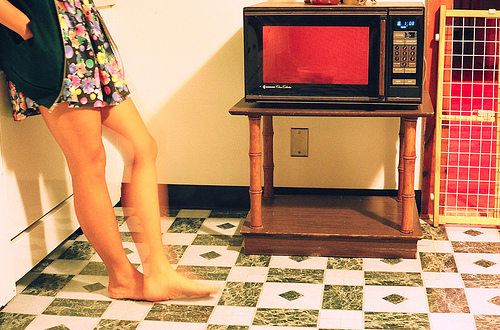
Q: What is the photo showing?
A: It is showing a kitchen.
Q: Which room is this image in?
A: It is at the kitchen.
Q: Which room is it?
A: It is a kitchen.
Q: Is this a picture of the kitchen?
A: Yes, it is showing the kitchen.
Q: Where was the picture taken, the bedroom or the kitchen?
A: It was taken at the kitchen.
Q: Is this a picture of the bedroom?
A: No, the picture is showing the kitchen.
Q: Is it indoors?
A: Yes, it is indoors.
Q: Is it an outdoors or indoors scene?
A: It is indoors.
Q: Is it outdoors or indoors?
A: It is indoors.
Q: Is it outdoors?
A: No, it is indoors.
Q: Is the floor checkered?
A: Yes, the floor is checkered.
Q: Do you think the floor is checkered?
A: Yes, the floor is checkered.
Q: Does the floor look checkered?
A: Yes, the floor is checkered.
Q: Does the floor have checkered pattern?
A: Yes, the floor is checkered.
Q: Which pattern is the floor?
A: The floor is checkered.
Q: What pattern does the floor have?
A: The floor has checkered pattern.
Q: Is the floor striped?
A: No, the floor is checkered.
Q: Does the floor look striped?
A: No, the floor is checkered.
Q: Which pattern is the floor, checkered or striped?
A: The floor is checkered.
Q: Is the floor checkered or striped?
A: The floor is checkered.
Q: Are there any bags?
A: No, there are no bags.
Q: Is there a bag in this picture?
A: No, there are no bags.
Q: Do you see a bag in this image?
A: No, there are no bags.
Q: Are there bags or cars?
A: No, there are no bags or cars.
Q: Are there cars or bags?
A: No, there are no bags or cars.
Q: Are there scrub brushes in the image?
A: No, there are no scrub brushes.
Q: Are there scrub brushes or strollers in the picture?
A: No, there are no scrub brushes or strollers.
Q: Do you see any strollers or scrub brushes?
A: No, there are no scrub brushes or strollers.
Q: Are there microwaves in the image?
A: Yes, there is a microwave.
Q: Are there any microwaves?
A: Yes, there is a microwave.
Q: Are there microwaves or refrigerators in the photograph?
A: Yes, there is a microwave.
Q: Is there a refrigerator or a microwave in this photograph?
A: Yes, there is a microwave.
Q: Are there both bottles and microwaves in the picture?
A: No, there is a microwave but no bottles.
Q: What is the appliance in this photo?
A: The appliance is a microwave.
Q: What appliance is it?
A: The appliance is a microwave.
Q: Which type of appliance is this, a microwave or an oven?
A: This is a microwave.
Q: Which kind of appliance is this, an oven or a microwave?
A: This is a microwave.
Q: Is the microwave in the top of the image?
A: Yes, the microwave is in the top of the image.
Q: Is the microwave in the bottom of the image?
A: No, the microwave is in the top of the image.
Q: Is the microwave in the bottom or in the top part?
A: The microwave is in the top of the image.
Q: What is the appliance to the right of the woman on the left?
A: The appliance is a microwave.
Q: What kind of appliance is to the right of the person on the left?
A: The appliance is a microwave.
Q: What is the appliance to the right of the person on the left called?
A: The appliance is a microwave.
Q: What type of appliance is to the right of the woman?
A: The appliance is a microwave.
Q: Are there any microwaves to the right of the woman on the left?
A: Yes, there is a microwave to the right of the woman.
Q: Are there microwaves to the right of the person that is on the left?
A: Yes, there is a microwave to the right of the woman.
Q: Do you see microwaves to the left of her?
A: No, the microwave is to the right of the woman.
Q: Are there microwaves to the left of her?
A: No, the microwave is to the right of the woman.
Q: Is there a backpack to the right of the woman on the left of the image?
A: No, there is a microwave to the right of the woman.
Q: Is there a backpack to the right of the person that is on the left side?
A: No, there is a microwave to the right of the woman.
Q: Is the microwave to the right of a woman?
A: Yes, the microwave is to the right of a woman.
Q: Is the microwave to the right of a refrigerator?
A: No, the microwave is to the right of a woman.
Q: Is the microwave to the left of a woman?
A: No, the microwave is to the right of a woman.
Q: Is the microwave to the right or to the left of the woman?
A: The microwave is to the right of the woman.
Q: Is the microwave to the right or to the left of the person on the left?
A: The microwave is to the right of the woman.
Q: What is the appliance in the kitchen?
A: The appliance is a microwave.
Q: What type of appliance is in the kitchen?
A: The appliance is a microwave.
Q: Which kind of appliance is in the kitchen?
A: The appliance is a microwave.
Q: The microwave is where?
A: The microwave is in the kitchen.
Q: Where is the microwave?
A: The microwave is in the kitchen.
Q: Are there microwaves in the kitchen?
A: Yes, there is a microwave in the kitchen.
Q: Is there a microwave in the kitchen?
A: Yes, there is a microwave in the kitchen.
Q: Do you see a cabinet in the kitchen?
A: No, there is a microwave in the kitchen.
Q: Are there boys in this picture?
A: No, there are no boys.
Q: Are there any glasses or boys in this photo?
A: No, there are no boys or glasses.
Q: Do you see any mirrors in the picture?
A: No, there are no mirrors.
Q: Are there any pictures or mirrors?
A: No, there are no mirrors or pictures.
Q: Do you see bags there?
A: No, there are no bags.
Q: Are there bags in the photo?
A: No, there are no bags.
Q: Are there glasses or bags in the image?
A: No, there are no bags or glasses.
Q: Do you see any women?
A: Yes, there is a woman.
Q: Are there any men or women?
A: Yes, there is a woman.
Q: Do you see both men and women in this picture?
A: No, there is a woman but no men.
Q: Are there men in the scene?
A: No, there are no men.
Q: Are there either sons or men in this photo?
A: No, there are no men or sons.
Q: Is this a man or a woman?
A: This is a woman.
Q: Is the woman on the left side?
A: Yes, the woman is on the left of the image.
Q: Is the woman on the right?
A: No, the woman is on the left of the image.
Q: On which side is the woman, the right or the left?
A: The woman is on the left of the image.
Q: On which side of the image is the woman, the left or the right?
A: The woman is on the left of the image.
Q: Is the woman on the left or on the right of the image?
A: The woman is on the left of the image.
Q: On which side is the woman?
A: The woman is on the left of the image.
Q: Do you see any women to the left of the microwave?
A: Yes, there is a woman to the left of the microwave.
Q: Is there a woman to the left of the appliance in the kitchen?
A: Yes, there is a woman to the left of the microwave.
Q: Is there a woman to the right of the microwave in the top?
A: No, the woman is to the left of the microwave.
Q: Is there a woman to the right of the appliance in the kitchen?
A: No, the woman is to the left of the microwave.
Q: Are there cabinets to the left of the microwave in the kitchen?
A: No, there is a woman to the left of the microwave.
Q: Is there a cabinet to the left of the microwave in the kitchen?
A: No, there is a woman to the left of the microwave.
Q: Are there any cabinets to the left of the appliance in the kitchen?
A: No, there is a woman to the left of the microwave.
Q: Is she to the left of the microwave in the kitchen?
A: Yes, the woman is to the left of the microwave.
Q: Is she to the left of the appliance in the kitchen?
A: Yes, the woman is to the left of the microwave.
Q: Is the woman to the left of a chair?
A: No, the woman is to the left of the microwave.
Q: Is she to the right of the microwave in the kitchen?
A: No, the woman is to the left of the microwave.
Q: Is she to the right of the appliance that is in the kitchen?
A: No, the woman is to the left of the microwave.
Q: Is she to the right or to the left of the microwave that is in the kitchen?
A: The woman is to the left of the microwave.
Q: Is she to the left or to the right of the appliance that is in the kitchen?
A: The woman is to the left of the microwave.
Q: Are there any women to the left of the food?
A: Yes, there is a woman to the left of the food.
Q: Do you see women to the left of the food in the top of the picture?
A: Yes, there is a woman to the left of the food.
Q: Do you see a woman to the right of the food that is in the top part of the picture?
A: No, the woman is to the left of the food.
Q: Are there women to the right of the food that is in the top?
A: No, the woman is to the left of the food.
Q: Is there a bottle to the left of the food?
A: No, there is a woman to the left of the food.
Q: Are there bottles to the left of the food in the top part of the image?
A: No, there is a woman to the left of the food.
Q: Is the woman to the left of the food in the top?
A: Yes, the woman is to the left of the food.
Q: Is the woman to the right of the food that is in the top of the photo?
A: No, the woman is to the left of the food.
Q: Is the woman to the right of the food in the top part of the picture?
A: No, the woman is to the left of the food.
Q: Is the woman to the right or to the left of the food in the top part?
A: The woman is to the left of the food.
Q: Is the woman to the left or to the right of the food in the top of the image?
A: The woman is to the left of the food.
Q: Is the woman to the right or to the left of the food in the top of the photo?
A: The woman is to the left of the food.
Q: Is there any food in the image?
A: Yes, there is food.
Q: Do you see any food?
A: Yes, there is food.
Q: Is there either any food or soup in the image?
A: Yes, there is food.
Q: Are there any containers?
A: No, there are no containers.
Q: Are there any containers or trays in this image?
A: No, there are no containers or trays.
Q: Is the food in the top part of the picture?
A: Yes, the food is in the top of the image.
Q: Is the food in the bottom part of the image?
A: No, the food is in the top of the image.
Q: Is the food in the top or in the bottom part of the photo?
A: The food is in the top of the image.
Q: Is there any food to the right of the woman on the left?
A: Yes, there is food to the right of the woman.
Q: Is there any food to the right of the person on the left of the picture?
A: Yes, there is food to the right of the woman.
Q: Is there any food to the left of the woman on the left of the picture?
A: No, the food is to the right of the woman.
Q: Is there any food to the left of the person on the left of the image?
A: No, the food is to the right of the woman.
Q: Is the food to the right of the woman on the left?
A: Yes, the food is to the right of the woman.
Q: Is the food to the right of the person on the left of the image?
A: Yes, the food is to the right of the woman.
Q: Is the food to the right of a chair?
A: No, the food is to the right of the woman.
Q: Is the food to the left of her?
A: No, the food is to the right of the woman.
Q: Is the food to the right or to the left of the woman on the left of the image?
A: The food is to the right of the woman.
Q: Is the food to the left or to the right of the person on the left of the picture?
A: The food is to the right of the woman.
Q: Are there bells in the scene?
A: No, there are no bells.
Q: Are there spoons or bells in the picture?
A: No, there are no bells or spoons.